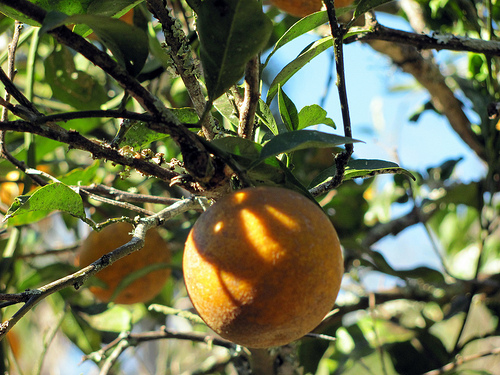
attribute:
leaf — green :
[245, 130, 365, 174]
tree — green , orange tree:
[1, 0, 498, 372]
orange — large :
[179, 189, 344, 348]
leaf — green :
[78, 157, 100, 187]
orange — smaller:
[72, 214, 170, 300]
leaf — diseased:
[116, 109, 201, 152]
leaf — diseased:
[4, 182, 91, 227]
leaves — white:
[190, 1, 275, 114]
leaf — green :
[110, 105, 206, 151]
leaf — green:
[53, 59, 247, 189]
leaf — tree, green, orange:
[250, 25, 408, 103]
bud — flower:
[156, 152, 168, 165]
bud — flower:
[138, 146, 154, 162]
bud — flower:
[167, 156, 182, 171]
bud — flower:
[120, 143, 135, 157]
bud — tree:
[70, 280, 85, 292]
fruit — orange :
[183, 191, 345, 356]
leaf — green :
[242, 125, 377, 192]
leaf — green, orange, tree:
[156, 2, 303, 127]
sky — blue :
[270, 12, 487, 183]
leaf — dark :
[330, 153, 425, 185]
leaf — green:
[257, 3, 357, 73]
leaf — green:
[34, 4, 156, 88]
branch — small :
[314, 2, 356, 198]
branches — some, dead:
[5, 2, 277, 184]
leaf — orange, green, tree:
[281, 129, 403, 192]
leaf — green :
[277, 81, 297, 131]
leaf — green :
[267, 87, 297, 142]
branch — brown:
[0, 180, 198, 324]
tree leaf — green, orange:
[258, 124, 360, 172]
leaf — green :
[154, 54, 336, 144]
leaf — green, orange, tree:
[261, 119, 361, 167]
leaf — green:
[246, 123, 361, 160]